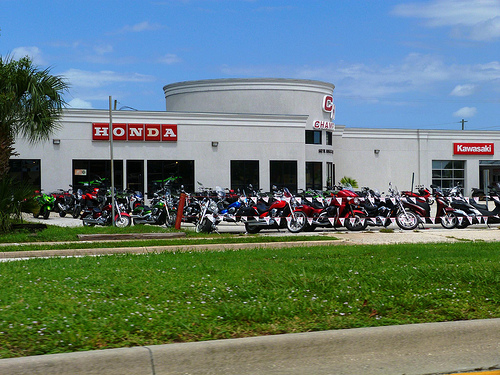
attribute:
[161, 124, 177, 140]
tile — red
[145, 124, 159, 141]
tile — red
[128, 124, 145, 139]
tile — red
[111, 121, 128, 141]
tile — red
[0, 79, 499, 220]
building — dealership, light gray, white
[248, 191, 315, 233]
bike — red, for sale, lined up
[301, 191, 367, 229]
bike — red, for sale, lined up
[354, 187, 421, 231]
bike — lined up, for sale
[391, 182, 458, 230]
bike — lined up, for sale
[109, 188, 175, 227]
bike — lined up, for sale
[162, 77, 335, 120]
middle — rounded, round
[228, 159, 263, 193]
window — dark, large, paneled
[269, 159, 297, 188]
window — dark, large, paneled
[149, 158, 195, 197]
window — large, dark, paneled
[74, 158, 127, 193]
window — large, dark, paneled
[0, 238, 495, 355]
grass — green, thick, brown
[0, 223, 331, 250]
grass — green, thick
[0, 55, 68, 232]
tree — large, palm, green, tall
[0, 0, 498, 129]
sky — blue, overhead, clear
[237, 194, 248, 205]
banner flag — white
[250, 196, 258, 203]
banner flag — white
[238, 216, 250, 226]
banner flag — white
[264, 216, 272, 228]
banner flag — white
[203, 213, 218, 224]
banner flag — white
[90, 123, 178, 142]
sign — white, red, honda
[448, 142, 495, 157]
sign — red, white, kawasaki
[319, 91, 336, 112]
sign — red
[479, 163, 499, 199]
garage — open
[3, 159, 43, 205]
garage — closed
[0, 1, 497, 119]
clouds — white, white+, wispy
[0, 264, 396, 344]
flowers — growing, white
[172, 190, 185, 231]
pole — red, metal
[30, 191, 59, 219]
bike — lime green, for sale, green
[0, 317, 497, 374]
cement — gray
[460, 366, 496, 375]
line — yellow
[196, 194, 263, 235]
bike — for sale, blue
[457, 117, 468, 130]
pole — telephone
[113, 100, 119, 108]
pole — telephone